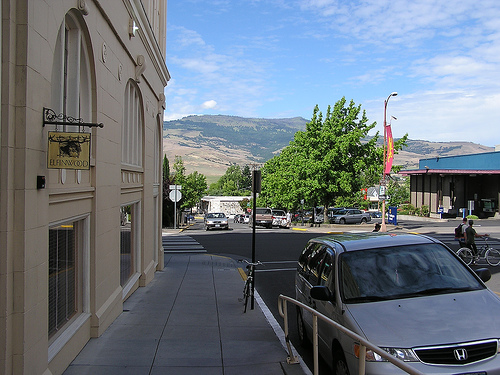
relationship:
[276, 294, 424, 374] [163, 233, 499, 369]
railing next to road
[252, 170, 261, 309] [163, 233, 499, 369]
post next to road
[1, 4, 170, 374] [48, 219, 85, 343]
building has window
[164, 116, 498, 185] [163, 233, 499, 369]
mountain behind road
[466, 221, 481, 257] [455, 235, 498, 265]
person next to bike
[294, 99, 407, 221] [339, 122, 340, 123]
tree has leaf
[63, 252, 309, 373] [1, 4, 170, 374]
sidewalk next to building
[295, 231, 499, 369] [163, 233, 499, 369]
car on road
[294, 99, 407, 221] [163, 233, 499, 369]
tree across road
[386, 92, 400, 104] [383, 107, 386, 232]
lamp has post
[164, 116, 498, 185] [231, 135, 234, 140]
mountain has tree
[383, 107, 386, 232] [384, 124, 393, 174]
post for advertisement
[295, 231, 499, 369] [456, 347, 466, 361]
car has symbol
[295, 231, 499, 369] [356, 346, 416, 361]
car has headlight